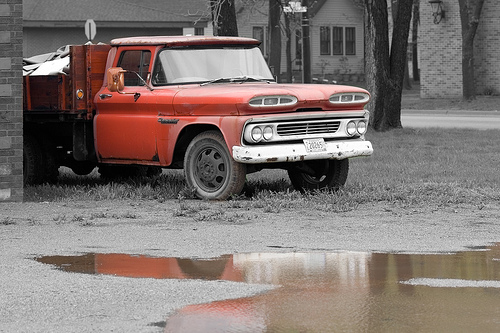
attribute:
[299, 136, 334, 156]
license plate — black, white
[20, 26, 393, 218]
truck — old, red, rusty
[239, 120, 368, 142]
headlights — clear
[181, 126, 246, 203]
front tire — black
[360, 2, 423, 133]
tree — split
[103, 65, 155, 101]
mirror — orange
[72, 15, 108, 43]
sign — stop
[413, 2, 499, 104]
building — brick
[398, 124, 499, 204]
grass — ground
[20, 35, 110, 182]
truck bed — full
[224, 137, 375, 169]
bumper — rusty, white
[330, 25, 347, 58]
window — rectangle